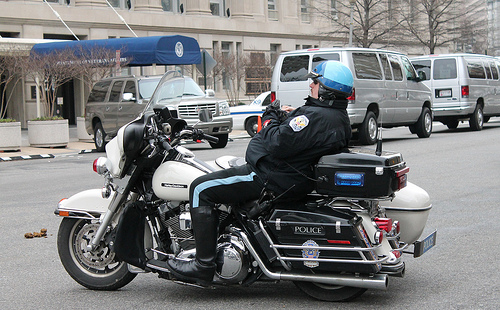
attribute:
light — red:
[459, 82, 469, 99]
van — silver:
[276, 51, 433, 132]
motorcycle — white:
[41, 67, 422, 304]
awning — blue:
[23, 35, 217, 82]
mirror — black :
[413, 69, 428, 81]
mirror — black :
[118, 91, 135, 101]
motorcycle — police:
[32, 90, 447, 291]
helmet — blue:
[308, 65, 356, 95]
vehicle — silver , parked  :
[82, 69, 237, 154]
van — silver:
[422, 43, 498, 109]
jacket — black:
[235, 104, 363, 175]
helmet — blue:
[297, 53, 363, 97]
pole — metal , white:
[40, 0, 81, 40]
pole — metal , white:
[104, 0, 138, 36]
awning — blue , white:
[24, 33, 209, 78]